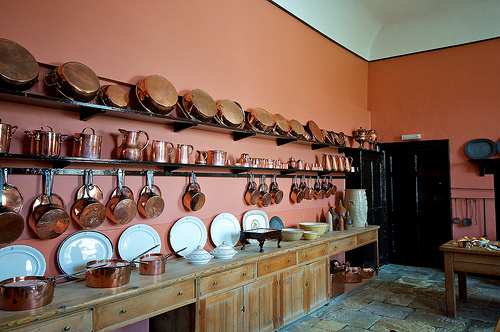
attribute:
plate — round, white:
[118, 221, 162, 259]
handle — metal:
[243, 267, 250, 277]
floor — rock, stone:
[289, 247, 498, 331]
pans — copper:
[26, 167, 212, 217]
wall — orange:
[2, 1, 406, 262]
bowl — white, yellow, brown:
[300, 220, 326, 236]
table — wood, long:
[23, 221, 387, 331]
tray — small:
[243, 225, 288, 249]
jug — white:
[343, 187, 369, 229]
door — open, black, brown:
[387, 140, 445, 266]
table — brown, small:
[439, 236, 500, 319]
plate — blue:
[271, 212, 284, 235]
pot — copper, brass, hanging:
[133, 174, 159, 211]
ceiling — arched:
[286, 1, 500, 56]